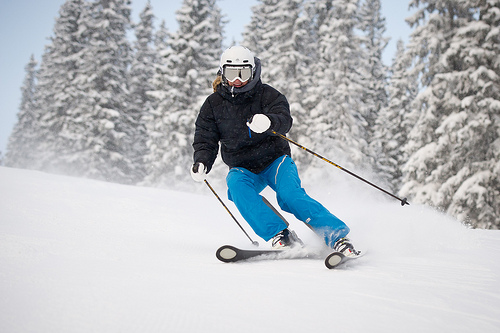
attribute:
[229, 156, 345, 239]
pants — blue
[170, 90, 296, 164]
jacket — black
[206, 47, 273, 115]
woman — skiing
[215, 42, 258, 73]
helmet — white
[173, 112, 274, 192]
gloves — white